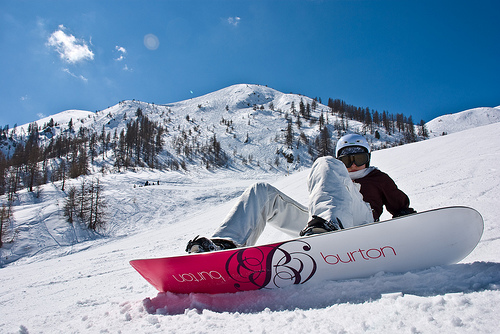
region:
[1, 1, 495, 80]
The sky is clear blue.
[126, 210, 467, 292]
The board is pink and white.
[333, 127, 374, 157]
Her helmet is white.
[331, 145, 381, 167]
Her goggles are black.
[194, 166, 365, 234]
Her pants are white.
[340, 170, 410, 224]
Her jacket is black.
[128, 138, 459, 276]
She is sitting.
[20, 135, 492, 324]
The ground is snow covered.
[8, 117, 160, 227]
The trees are bare.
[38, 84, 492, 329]
She is snow boarding.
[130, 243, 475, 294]
a snowboard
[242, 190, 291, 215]
person is wearing white pants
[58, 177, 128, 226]
trees on the hill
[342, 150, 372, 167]
snow goggles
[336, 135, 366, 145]
a white helmet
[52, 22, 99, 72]
cloud in the sky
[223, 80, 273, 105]
the top of the mountain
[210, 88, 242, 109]
snow is on the mountain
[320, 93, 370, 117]
the trees are green on the hill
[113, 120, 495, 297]
snowboarder in the snow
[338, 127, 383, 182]
helmet on snowboarder's head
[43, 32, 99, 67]
white cloud in the sky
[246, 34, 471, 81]
blue sky in the distance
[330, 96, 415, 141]
pine trees on the mountain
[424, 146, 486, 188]
white snow on the ground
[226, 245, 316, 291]
design on a snowboard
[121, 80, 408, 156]
mountain in the distance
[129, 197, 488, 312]
snowboard in the snow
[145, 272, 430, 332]
shadow casted in the snow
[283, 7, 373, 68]
blue sky above land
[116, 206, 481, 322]
board in the snow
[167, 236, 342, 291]
white and pink board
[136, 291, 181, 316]
shadow on the ground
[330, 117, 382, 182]
head of the person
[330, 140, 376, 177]
goggles on the person's face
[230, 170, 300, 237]
white shorts on person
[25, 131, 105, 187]
trees in the distance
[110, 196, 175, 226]
snow on the ground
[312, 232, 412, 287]
writing on bottom of board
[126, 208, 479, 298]
red and white snow board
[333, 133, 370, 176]
blue plastic helmet on head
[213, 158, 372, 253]
white padded snow pants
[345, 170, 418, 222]
black padded winter jacket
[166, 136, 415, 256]
man sitting in snow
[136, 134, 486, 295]
man snow boarding on hill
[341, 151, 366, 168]
black goggles on face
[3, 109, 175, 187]
green trees on mountain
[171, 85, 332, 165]
mountain covered in snow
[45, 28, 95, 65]
white cloud in sky